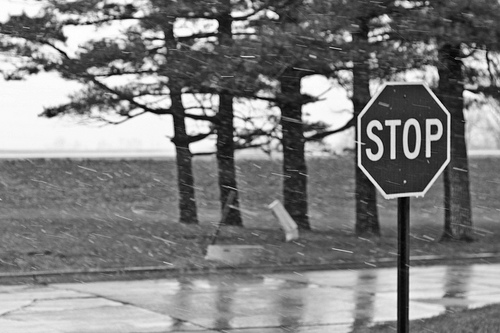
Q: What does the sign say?
A: Stop.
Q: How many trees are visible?
A: Five.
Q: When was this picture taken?
A: Day time.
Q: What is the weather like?
A: Raining.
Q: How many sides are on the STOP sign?
A: Eight.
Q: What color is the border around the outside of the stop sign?
A: White.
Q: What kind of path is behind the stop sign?
A: Sidewalk.